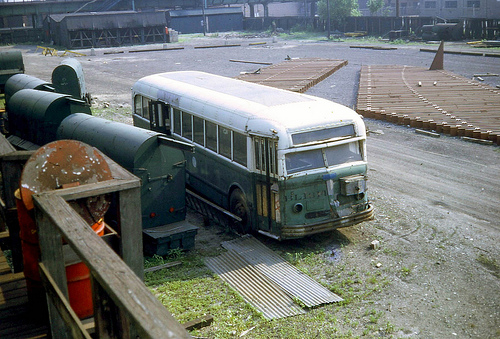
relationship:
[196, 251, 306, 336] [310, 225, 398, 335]
fence on ground